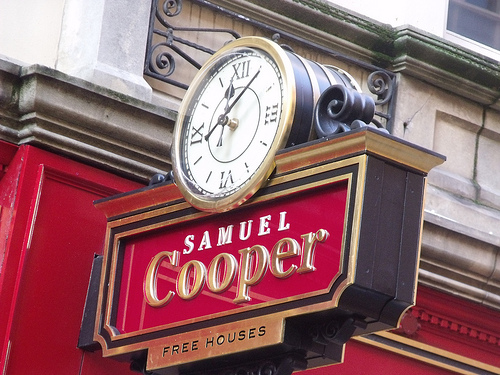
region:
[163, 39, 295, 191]
The clock face is white.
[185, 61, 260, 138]
The hands are black.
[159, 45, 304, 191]
The numbers are black.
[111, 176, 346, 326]
The sign is red.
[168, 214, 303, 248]
The lettering is white.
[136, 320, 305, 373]
The sign is gold.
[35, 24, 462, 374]
The clock is on the sign.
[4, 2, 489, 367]
The sign is attached to the wall.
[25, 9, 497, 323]
The edge is black.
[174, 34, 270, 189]
A clock above the sign.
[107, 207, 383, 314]
A sign below the clock.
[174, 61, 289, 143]
The clock is in roman numbers.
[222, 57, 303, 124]
The numbers on the clock is black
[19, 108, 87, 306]
The building is red.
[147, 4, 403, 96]
Black bars over the window.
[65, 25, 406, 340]
The sign and clock is attached to each other.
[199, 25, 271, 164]
The time on the clock is 12:05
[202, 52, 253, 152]
The hands on the clock is black.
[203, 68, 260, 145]
the hands on the clock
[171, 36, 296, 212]
the clock on the sign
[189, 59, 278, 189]
the roman numerals on the clock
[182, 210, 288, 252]
the word SAMUEL on the sign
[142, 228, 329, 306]
the word "Cooper" on the sign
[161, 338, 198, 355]
the word "FREE" on the sign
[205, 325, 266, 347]
the word "HOUSES" on the sign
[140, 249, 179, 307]
the "C" on the sign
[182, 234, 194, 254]
the "S" on the sign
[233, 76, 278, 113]
Black hand on clock.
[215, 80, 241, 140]
Black hand on clock.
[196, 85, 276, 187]
Black numbers on clock.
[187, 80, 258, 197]
Face on clock is white.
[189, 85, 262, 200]
Face on clock is round.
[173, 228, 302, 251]
White word on red sign.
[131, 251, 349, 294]
Gold word on sign.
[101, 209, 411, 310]
Large sign attached to building.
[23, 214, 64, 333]
Building near clock is red.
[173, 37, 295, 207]
clock on top of sign.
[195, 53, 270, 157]
the time is a little after twelve PM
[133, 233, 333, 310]
golden letters on sign that spell Cooper.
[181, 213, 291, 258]
white letters on sign that spell Samuel.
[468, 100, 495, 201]
crack in the framework.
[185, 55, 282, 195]
clock face has Roman numerals.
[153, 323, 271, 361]
bottom of sign says Free Houses.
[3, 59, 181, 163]
the trim is brown.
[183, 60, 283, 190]
the clock face has white background.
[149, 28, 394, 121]
black wrought iron behind the clock.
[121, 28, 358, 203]
Clock on a sign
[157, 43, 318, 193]
Round clock on a sign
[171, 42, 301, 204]
Clock with white face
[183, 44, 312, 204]
Clock with black hands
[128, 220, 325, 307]
Writing on the sign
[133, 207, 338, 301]
Writing on red sign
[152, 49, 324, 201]
White clock on red sign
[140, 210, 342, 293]
Writing underneath the clock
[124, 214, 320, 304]
Writing underneath white clock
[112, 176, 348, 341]
white and gold letters on a red background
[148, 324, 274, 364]
black letters on a gold background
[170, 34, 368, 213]
black and gold clock with white face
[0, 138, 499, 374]
bright red wall on the side of a building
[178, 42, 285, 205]
white clock face with black hands and numerals